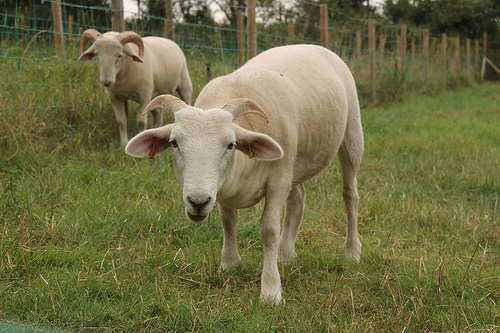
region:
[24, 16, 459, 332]
sheep in a field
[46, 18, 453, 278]
two sheep in a field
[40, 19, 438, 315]
white sheep in a field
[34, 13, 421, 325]
two white sheep in a field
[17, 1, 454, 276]
sheep behind a fence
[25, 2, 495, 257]
white sheep behind a fence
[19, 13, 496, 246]
two sheep behind a fence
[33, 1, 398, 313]
two white sheep behind a fence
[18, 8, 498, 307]
sheep in a fenced in area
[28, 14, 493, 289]
two sheep in a fenced in area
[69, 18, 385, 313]
two male sheep in pasture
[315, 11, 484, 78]
fence has wooden posts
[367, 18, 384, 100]
post is made of wood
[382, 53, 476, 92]
weeds along fence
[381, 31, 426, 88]
fence is made of metal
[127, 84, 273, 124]
sheep has two horns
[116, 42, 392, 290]
sheep is white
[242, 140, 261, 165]
sheep has yellow tag in ear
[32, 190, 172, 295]
grass is lush and green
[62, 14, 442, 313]
sheep are in a pasture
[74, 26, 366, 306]
two goats standing in the grass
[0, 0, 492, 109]
wooden fence posts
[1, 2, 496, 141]
barbed wire fence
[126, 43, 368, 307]
goat with horns on top of the head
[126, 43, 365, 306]
orange tag in the goat's right ear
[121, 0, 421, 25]
cloudy sky seen through the trees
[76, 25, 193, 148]
goat with long curved horns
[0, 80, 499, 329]
grassy field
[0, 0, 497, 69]
trees behind the fence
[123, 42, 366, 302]
goat looking at the camer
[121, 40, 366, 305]
a white sheep standing in the grass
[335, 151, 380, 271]
the back leg of a sheep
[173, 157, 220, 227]
the nose of a sheep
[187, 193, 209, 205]
the nostrils on a sheep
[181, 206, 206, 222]
the mouth on a sheep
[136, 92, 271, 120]
the horns on a sheep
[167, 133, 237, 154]
the eyes on a sheep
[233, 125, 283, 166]
the ear on a sheep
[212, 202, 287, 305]
the front legs on a sheep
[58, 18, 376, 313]
two sheep in a pasture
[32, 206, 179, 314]
The grass on the ground is green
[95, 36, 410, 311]
The goat is looking forward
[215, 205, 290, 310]
The legs on the goat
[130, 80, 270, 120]
The horns on the goat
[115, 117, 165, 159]
The ear of the goat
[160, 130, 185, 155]
The eye of the goat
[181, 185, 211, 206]
The nose of the goat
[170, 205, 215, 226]
The mouth of the goat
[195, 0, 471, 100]
The gate separating the goats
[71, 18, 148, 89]
The head of the goat